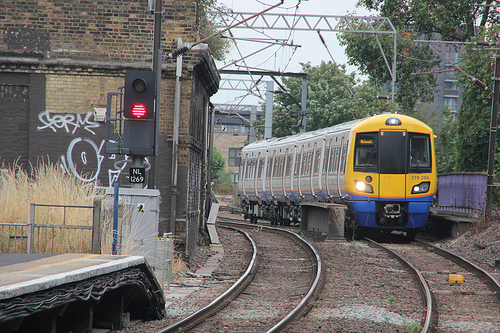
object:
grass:
[404, 322, 424, 331]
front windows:
[355, 131, 431, 173]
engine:
[328, 112, 437, 242]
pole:
[110, 181, 118, 254]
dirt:
[218, 216, 499, 333]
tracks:
[162, 209, 497, 331]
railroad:
[156, 225, 497, 332]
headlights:
[410, 181, 430, 193]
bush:
[296, 75, 356, 118]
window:
[245, 161, 251, 181]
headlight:
[356, 182, 366, 192]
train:
[236, 114, 440, 241]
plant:
[1, 150, 125, 248]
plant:
[451, 33, 498, 173]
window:
[409, 131, 432, 172]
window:
[352, 133, 376, 172]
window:
[272, 153, 286, 175]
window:
[323, 148, 334, 172]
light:
[132, 101, 146, 116]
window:
[299, 152, 312, 177]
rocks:
[307, 297, 419, 329]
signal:
[120, 69, 158, 157]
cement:
[195, 244, 225, 279]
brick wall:
[1, 1, 200, 236]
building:
[0, 0, 221, 252]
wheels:
[270, 206, 290, 225]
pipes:
[200, 180, 211, 237]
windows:
[311, 147, 329, 173]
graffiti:
[38, 104, 112, 187]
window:
[339, 145, 348, 172]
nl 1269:
[128, 167, 146, 183]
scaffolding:
[202, 0, 395, 86]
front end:
[345, 112, 436, 241]